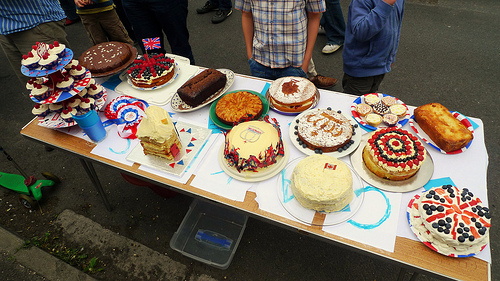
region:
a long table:
[48, 43, 493, 271]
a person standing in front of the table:
[229, 2, 328, 67]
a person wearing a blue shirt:
[342, 1, 419, 92]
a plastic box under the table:
[172, 196, 242, 266]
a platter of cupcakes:
[20, 30, 95, 112]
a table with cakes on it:
[21, 31, 493, 278]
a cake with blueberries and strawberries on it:
[416, 184, 486, 251]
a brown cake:
[173, 67, 233, 107]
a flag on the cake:
[139, 32, 161, 49]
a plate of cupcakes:
[348, 89, 396, 126]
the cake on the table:
[409, 177, 491, 263]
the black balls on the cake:
[429, 210, 485, 239]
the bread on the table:
[414, 97, 473, 157]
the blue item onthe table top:
[68, 103, 110, 145]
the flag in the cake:
[139, 33, 164, 68]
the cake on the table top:
[15, 35, 488, 263]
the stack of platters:
[8, 40, 104, 131]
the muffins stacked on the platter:
[19, 38, 99, 128]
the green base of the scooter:
[0, 168, 71, 205]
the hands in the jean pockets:
[242, 45, 310, 80]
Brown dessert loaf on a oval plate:
[167, 60, 237, 115]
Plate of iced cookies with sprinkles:
[354, 85, 407, 134]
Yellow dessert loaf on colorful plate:
[413, 100, 475, 153]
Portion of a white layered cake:
[130, 98, 191, 172]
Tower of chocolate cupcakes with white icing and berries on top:
[9, 39, 114, 144]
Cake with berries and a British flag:
[126, 33, 178, 92]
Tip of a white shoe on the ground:
[317, 34, 341, 59]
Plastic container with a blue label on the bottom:
[165, 196, 256, 270]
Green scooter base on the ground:
[0, 143, 62, 208]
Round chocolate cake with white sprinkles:
[77, 36, 132, 74]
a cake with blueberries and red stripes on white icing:
[413, 181, 496, 261]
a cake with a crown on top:
[292, 107, 359, 158]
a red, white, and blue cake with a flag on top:
[118, 35, 180, 87]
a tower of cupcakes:
[19, 37, 102, 143]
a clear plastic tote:
[168, 196, 247, 271]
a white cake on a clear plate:
[290, 153, 355, 214]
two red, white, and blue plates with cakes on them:
[348, 93, 474, 155]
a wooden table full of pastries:
[20, 53, 491, 278]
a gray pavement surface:
[2, 3, 495, 279]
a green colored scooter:
[0, 140, 60, 208]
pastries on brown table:
[110, 30, 499, 267]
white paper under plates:
[93, 53, 463, 275]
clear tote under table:
[168, 183, 244, 278]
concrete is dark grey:
[85, 194, 156, 270]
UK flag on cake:
[128, 35, 163, 54]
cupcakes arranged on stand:
[28, 31, 92, 131]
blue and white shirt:
[248, 2, 308, 57]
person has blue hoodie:
[339, 1, 411, 88]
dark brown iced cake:
[76, 39, 135, 79]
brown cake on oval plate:
[163, 65, 242, 122]